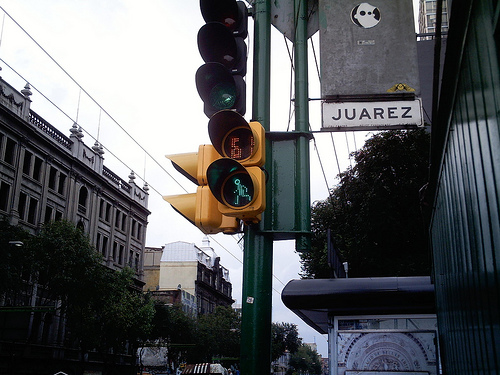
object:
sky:
[0, 0, 380, 349]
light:
[219, 123, 258, 162]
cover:
[205, 108, 259, 158]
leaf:
[99, 311, 108, 319]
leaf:
[40, 257, 46, 262]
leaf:
[54, 241, 60, 243]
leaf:
[80, 266, 84, 271]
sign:
[323, 98, 427, 129]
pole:
[238, 0, 279, 374]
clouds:
[0, 0, 182, 93]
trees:
[0, 217, 38, 310]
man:
[280, 330, 332, 374]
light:
[208, 78, 239, 110]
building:
[0, 67, 148, 374]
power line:
[0, 5, 192, 194]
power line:
[0, 57, 167, 201]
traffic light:
[194, 0, 246, 115]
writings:
[329, 103, 417, 121]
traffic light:
[205, 111, 261, 211]